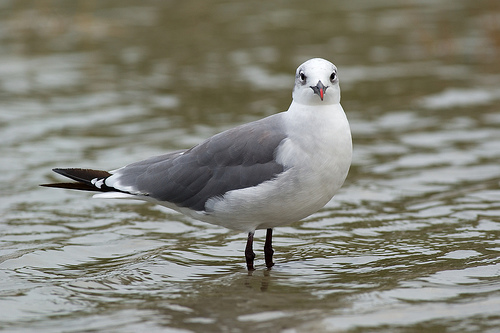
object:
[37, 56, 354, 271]
bird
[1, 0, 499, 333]
water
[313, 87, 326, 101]
beak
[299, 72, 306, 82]
eye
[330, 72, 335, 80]
eye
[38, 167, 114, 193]
tail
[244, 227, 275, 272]
legs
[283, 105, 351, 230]
chest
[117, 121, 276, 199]
wing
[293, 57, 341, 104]
bird head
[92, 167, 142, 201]
feathers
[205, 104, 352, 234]
breast plumage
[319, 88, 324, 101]
orange strip